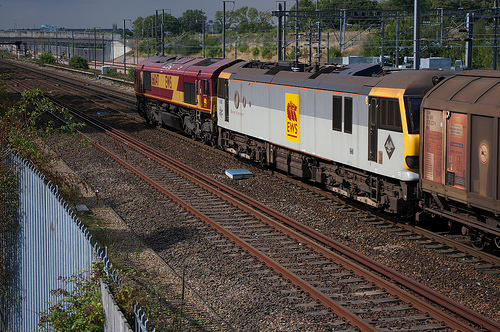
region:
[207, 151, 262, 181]
A silver box in the middle of the tracks.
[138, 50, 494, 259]
A train on the tracks.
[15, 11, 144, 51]
A bridge in the background.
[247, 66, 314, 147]
The gray train has a yellow sign on it.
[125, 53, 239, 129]
The las train is red and yellow.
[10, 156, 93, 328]
The cliff is next to the tracks.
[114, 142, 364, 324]
The tracks are on the ground.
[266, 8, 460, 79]
Wires on pole next to the train.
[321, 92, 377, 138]
Two windows on the gray train.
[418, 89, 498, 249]
The train car is old and rusty.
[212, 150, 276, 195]
the blue item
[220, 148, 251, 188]
the blue item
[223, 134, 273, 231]
the blue item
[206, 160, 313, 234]
the blue item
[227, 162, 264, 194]
the blue item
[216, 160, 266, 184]
a blue object near a train.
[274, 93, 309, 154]
a yellow sign on a train.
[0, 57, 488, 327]
a rusted set of train tracks.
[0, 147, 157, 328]
a blue iron fence.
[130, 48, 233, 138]
a red train engine.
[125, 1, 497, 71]
a hill covered in trees.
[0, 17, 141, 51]
a bridge crossing a train track.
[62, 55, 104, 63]
a wild bush growing near tracks.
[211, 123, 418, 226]
wheels supporting a train.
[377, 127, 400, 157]
a sign on the side of a train.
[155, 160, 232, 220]
this is a railway line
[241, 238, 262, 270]
this is a metal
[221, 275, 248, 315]
this is a small rock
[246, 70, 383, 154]
this is a train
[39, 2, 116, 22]
this is the sky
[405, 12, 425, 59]
this is a pole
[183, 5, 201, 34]
this is a tree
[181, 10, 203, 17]
the leaves are green in color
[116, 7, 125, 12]
the sky is blue in color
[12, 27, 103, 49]
this is a building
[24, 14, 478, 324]
three train cars parked on tracks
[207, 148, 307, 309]
train tracks on ground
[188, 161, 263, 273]
metal posts on train track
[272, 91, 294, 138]
yellow and red logo on side of train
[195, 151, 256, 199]
blue and white object on the ground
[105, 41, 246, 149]
back red and yellow train car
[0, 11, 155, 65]
bridge in the background of the picture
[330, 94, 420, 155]
front window on train car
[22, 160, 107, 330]
grey metal gate next to tracks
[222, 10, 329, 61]
many power line poles